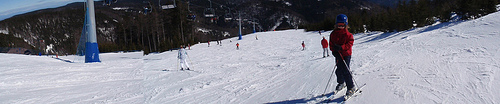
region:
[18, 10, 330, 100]
this ski slope is busy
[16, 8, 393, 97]
the photo is a panorama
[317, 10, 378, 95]
this skier has a red jacket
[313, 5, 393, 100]
the helmet is blue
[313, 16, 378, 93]
the skier has two poles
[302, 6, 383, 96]
the skier has black pants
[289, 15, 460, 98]
three skiers wear red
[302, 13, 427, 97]
the skier wears a helmet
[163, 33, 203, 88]
this skier wears a grey jacket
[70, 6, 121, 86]
the pole has blue trim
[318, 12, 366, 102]
The woman is skiing.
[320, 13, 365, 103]
The woman is on skis.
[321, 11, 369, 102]
The woman is on the snow.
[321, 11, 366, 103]
The woman is holding ski poles.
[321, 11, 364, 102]
The woman is wearing a helmet.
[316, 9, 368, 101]
The woman is wearing sunglasses.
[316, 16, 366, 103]
The woman is wearing a jacket.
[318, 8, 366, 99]
The woman is wearing black pants.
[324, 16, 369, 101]
The woman is wearing ski boats.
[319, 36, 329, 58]
The man in the background is wearing a red jacket.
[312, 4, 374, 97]
A boy standing up on his ski skates.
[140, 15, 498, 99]
Many people visiting the ski resort.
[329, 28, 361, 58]
Warm ski jacket suitable for the weather.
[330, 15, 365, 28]
Blue helmet worn to protect the boy's head.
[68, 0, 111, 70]
Blue and grey electrical pole.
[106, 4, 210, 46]
Trees lining up the ski arena.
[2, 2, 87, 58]
Mountains can be seen from the ski resort.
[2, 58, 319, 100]
The ground was cover with snow.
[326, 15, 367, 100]
The boy trying to balance himself using ski poles.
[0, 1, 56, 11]
Ocean can be seen in the horizon.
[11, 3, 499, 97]
It was a beautiful winter.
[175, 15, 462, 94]
Many people skiing at the resort.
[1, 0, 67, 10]
Ocean water can be seen in the horizon.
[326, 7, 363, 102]
The boy standing trying to balance himself.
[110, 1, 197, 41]
Many trees surrounding the ski resort.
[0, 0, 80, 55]
Beautiful mountains can be seen in the background.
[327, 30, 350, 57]
Ski jacket suitable for the weather.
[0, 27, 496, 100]
Thick snow covering the ground.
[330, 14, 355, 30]
Blue helmet to protect the boy's head.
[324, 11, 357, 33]
head of the skier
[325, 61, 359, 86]
legs of the skier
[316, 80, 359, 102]
skis on the ground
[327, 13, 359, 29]
blue helmet on kid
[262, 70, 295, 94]
snow on the ground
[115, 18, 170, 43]
trees in the distance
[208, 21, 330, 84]
people in the background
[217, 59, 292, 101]
tracks in the snow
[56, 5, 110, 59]
pole in the snow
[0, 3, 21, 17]
sky in the background